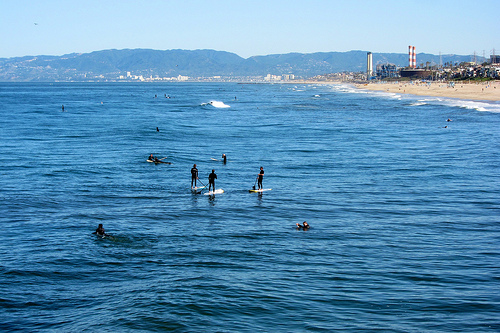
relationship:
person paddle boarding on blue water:
[250, 164, 268, 191] [0, 81, 500, 332]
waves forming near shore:
[318, 82, 498, 121] [366, 80, 494, 102]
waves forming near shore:
[198, 94, 240, 117] [366, 80, 494, 102]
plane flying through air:
[27, 10, 44, 27] [4, 0, 490, 53]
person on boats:
[190, 162, 200, 185] [180, 178, 271, 202]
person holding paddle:
[186, 162, 205, 185] [193, 173, 206, 187]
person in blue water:
[255, 164, 265, 191] [0, 81, 500, 332]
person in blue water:
[283, 214, 325, 246] [0, 81, 500, 332]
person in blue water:
[206, 163, 219, 195] [0, 81, 500, 332]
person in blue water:
[95, 221, 105, 238] [0, 81, 500, 332]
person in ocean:
[255, 164, 265, 191] [328, 99, 399, 202]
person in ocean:
[255, 164, 265, 191] [328, 105, 441, 211]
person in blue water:
[59, 103, 65, 109] [0, 81, 500, 332]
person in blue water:
[294, 219, 309, 231] [0, 81, 500, 332]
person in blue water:
[156, 125, 160, 132] [0, 81, 500, 332]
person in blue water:
[445, 116, 454, 121] [0, 81, 500, 332]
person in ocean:
[255, 164, 265, 191] [74, 117, 365, 172]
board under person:
[246, 184, 281, 203] [256, 162, 263, 188]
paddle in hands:
[254, 159, 270, 193] [256, 170, 272, 178]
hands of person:
[256, 170, 272, 178] [255, 164, 264, 188]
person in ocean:
[255, 164, 265, 191] [45, 79, 487, 280]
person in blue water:
[206, 168, 218, 191] [0, 81, 500, 332]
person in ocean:
[206, 167, 218, 192] [25, 70, 470, 330]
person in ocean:
[255, 164, 265, 191] [247, 105, 427, 169]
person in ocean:
[206, 167, 218, 188] [247, 105, 427, 169]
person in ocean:
[190, 162, 200, 185] [247, 105, 427, 169]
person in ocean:
[219, 152, 230, 164] [247, 105, 427, 169]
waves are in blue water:
[410, 96, 499, 114] [0, 81, 500, 332]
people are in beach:
[372, 62, 498, 114] [119, 74, 498, 114]